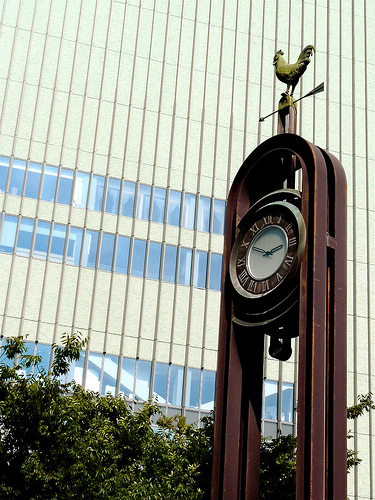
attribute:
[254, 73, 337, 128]
arrow — rusted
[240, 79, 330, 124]
arrow — iron, molded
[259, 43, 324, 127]
chicken windvane — metal, molded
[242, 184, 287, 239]
numeral — roman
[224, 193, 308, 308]
clock — big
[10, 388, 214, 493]
tree — green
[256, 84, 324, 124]
vane — weather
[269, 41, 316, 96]
rooster — rusted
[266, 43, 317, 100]
chicken replica — metal, molded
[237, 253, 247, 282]
numbers — roman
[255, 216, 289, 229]
numbers — roman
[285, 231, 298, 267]
numbers — roman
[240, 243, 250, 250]
numeral — roman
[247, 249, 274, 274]
interior — white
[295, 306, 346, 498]
pillar — brown, metal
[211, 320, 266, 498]
pillar — brown, metal